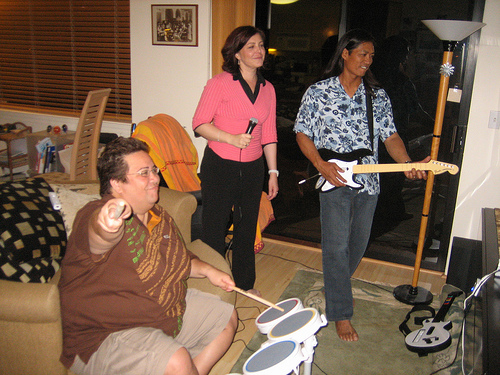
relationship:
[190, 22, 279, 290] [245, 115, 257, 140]
woman holds microphone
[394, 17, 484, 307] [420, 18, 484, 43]
floor lamp on shade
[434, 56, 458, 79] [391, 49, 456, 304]
bow on pole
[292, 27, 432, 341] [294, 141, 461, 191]
guitar man plays guitar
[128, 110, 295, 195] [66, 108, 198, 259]
blanket over chair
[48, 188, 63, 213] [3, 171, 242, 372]
wii remote on chair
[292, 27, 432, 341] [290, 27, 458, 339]
guitar man holds guitar man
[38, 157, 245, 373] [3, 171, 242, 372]
person on chair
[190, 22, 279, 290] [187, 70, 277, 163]
woman holds sweater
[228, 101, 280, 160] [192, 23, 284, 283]
microphone held by woman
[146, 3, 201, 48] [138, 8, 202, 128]
picture on wall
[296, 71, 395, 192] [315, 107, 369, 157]
shirt with pattern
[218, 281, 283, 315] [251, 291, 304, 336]
drumstick hitting drum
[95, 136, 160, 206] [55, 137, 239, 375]
head of person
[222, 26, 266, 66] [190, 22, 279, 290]
head of woman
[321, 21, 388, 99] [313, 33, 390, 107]
head of man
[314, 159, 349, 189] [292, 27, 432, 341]
hand of guitar man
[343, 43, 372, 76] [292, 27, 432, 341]
face of guitar man